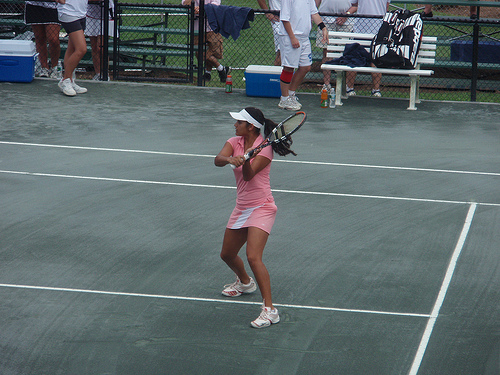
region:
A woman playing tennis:
[190, 85, 325, 335]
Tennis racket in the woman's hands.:
[232, 102, 319, 183]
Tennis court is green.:
[2, 54, 494, 368]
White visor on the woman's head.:
[220, 105, 267, 130]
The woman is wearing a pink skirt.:
[185, 187, 295, 235]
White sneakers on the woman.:
[212, 269, 292, 334]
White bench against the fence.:
[313, 12, 448, 107]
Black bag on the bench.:
[355, 6, 433, 78]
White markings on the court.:
[13, 139, 490, 370]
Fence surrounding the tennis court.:
[0, 11, 498, 109]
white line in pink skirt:
[221, 200, 277, 235]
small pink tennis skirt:
[216, 187, 287, 232]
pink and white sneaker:
[245, 302, 307, 327]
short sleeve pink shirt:
[198, 127, 308, 184]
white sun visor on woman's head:
[221, 102, 274, 127]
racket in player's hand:
[231, 97, 313, 170]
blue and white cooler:
[233, 62, 308, 101]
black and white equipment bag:
[375, 10, 431, 84]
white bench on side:
[318, 26, 443, 99]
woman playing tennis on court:
[171, 90, 338, 334]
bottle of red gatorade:
[225, 71, 232, 94]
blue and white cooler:
[244, 64, 281, 99]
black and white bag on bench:
[370, 11, 423, 71]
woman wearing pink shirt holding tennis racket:
[211, 92, 307, 334]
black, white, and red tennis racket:
[238, 106, 305, 163]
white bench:
[321, 29, 442, 110]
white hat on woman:
[226, 107, 269, 129]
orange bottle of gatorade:
[318, 88, 330, 109]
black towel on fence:
[202, 1, 254, 41]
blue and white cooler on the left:
[2, 39, 35, 83]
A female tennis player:
[207, 97, 311, 340]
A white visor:
[224, 100, 270, 146]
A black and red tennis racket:
[230, 102, 315, 171]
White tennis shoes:
[201, 269, 298, 336]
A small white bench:
[312, 18, 441, 115]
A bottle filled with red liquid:
[217, 67, 237, 99]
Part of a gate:
[92, 0, 206, 95]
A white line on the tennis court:
[375, 188, 487, 370]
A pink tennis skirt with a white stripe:
[209, 197, 292, 237]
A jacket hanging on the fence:
[187, 3, 269, 48]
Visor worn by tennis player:
[226, 105, 266, 131]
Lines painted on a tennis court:
[405, 291, 447, 328]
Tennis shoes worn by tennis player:
[250, 303, 285, 335]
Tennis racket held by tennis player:
[234, 108, 317, 165]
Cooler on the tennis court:
[238, 57, 285, 102]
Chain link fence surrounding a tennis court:
[197, 24, 239, 83]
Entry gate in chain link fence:
[106, 0, 208, 87]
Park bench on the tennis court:
[319, 19, 442, 116]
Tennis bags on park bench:
[370, 3, 425, 74]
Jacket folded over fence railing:
[196, 2, 264, 42]